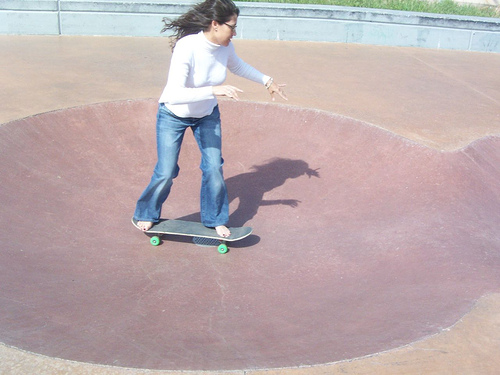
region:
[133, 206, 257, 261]
skateboard under a woman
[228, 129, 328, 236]
shadow on the ground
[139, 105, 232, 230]
jeans on a woman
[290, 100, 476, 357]
ramp at a skatepark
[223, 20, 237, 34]
glasses on a woman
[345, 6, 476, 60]
fence surrounding skate park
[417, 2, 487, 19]
green leaves from trees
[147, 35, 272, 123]
white sweater on a woman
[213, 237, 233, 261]
wheel on a skateboard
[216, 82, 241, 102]
right hand of a woman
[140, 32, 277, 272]
a lady is ona skating board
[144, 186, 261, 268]
the lady has no shoes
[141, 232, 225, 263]
wheels of skating board are green in color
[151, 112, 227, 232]
the pants ae blue in color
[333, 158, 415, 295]
the floor is brown in color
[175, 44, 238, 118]
the blouse ia white in color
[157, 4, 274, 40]
the hair is black i=and tall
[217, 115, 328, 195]
shadow of the lady on the groaund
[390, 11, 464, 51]
the wall is made of concrete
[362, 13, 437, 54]
wall is grey in color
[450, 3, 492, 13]
this is the grass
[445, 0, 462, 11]
the grass is short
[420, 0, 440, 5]
the grass is green in color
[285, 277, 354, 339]
this is the skating zone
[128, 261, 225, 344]
this is the ground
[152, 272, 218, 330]
the ground is made of cocncrete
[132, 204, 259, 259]
this is a skateboard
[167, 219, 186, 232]
the board is wooden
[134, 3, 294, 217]
this is a woman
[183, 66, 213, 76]
the blouse is white in color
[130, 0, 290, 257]
Woman riding a skateboard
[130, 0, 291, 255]
Woman riding barefoot on a skateboard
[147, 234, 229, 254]
Mint green wheels of a skateboard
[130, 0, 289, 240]
Woman wearing a white turtleneck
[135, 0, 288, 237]
Woman wearing blue jeans and barefoot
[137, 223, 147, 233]
red nailpolish on toes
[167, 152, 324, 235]
Shadow of a woman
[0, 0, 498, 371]
Cement skate park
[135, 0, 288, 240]
Woman wearing black glasses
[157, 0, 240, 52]
Long brunette hair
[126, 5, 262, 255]
a woman skateboarding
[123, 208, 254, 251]
woman is skateboarding barefoot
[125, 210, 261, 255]
skateboard is black with a mint green wheels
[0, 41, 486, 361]
a skateboarding park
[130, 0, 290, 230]
woman is wearing a white shirt and jeans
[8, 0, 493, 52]
a short cement wall in the back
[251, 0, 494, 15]
a patch of grass behind the wall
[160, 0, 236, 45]
woman is a brunette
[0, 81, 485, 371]
a concave circle skate in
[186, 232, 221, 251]
a drain underneath the skateboard